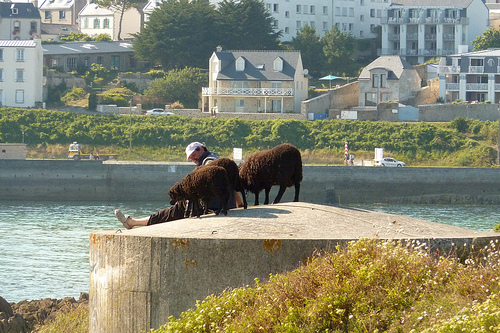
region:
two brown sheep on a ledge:
[162, 146, 303, 220]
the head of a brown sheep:
[160, 178, 190, 210]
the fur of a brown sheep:
[182, 173, 220, 198]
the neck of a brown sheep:
[172, 181, 192, 195]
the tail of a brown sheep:
[207, 166, 244, 194]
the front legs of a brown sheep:
[178, 195, 200, 222]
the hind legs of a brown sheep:
[208, 193, 242, 221]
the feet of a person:
[107, 201, 151, 236]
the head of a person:
[182, 135, 197, 166]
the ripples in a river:
[7, 208, 74, 282]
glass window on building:
[372, 73, 379, 87]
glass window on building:
[379, 72, 386, 85]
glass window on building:
[363, 89, 375, 104]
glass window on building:
[379, 88, 391, 101]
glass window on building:
[269, 75, 284, 92]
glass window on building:
[230, 80, 247, 91]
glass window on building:
[273, 55, 283, 70]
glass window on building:
[236, 60, 246, 71]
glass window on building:
[294, 3, 301, 13]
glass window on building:
[100, 17, 110, 27]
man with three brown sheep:
[109, 133, 308, 228]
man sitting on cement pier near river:
[99, 142, 234, 232]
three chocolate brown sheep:
[171, 142, 302, 218]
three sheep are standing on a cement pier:
[164, 144, 306, 221]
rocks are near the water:
[4, 279, 82, 321]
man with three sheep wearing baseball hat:
[183, 142, 215, 168]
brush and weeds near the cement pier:
[126, 225, 488, 320]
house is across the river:
[198, 43, 311, 124]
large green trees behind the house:
[125, 0, 280, 57]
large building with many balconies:
[376, 4, 481, 56]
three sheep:
[153, 147, 315, 206]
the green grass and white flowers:
[296, 259, 441, 320]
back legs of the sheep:
[271, 187, 301, 201]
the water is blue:
[3, 208, 66, 273]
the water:
[432, 205, 481, 226]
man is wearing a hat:
[183, 139, 205, 157]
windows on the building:
[295, 3, 319, 14]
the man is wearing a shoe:
[111, 207, 134, 230]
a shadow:
[236, 203, 287, 218]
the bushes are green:
[29, 112, 74, 132]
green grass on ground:
[164, 318, 184, 331]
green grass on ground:
[182, 307, 204, 327]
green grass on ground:
[214, 290, 237, 331]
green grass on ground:
[252, 304, 274, 330]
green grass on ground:
[285, 309, 296, 330]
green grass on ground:
[314, 288, 327, 318]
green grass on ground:
[334, 278, 354, 293]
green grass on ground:
[363, 259, 380, 282]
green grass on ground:
[348, 240, 370, 268]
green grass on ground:
[255, 274, 286, 287]